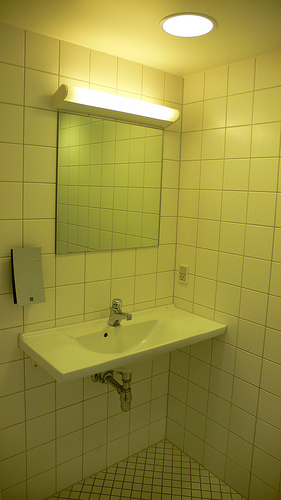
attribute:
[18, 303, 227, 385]
sink — white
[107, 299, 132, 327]
faucet — silver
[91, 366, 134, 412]
pipes — metal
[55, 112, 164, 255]
mirror — glass, mounted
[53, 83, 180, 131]
light — mounted, fluorescent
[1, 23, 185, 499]
wall — square, white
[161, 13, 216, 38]
light — round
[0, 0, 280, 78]
ceiling — white, grey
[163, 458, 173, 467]
tile — square